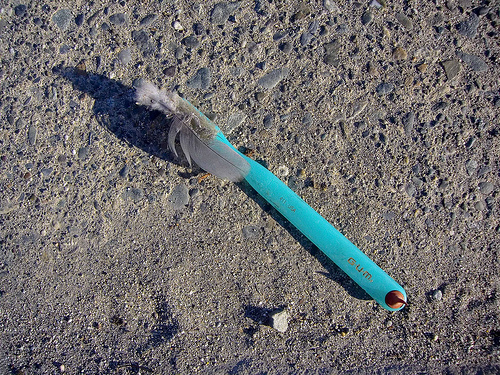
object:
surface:
[324, 40, 343, 72]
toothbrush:
[132, 79, 408, 313]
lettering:
[345, 253, 357, 267]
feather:
[132, 79, 253, 184]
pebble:
[77, 12, 87, 26]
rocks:
[299, 31, 311, 44]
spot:
[260, 69, 285, 89]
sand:
[52, 65, 64, 74]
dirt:
[243, 19, 287, 36]